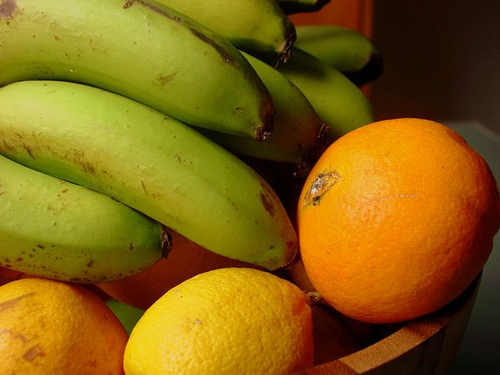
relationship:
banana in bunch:
[0, 0, 278, 143] [0, 1, 385, 284]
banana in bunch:
[0, 79, 301, 270] [0, 1, 385, 284]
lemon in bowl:
[122, 268, 314, 374] [296, 243, 493, 374]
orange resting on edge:
[298, 118, 499, 324] [399, 263, 486, 352]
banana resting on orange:
[0, 157, 171, 283] [1, 274, 130, 374]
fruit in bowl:
[0, 0, 497, 372] [296, 243, 493, 374]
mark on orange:
[0, 290, 31, 327] [1, 274, 130, 374]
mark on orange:
[26, 343, 47, 364] [1, 274, 130, 374]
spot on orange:
[311, 175, 324, 196] [298, 118, 499, 324]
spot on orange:
[311, 193, 322, 207] [298, 118, 499, 324]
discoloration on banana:
[185, 25, 236, 68] [0, 0, 278, 143]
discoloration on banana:
[257, 195, 278, 217] [0, 79, 301, 270]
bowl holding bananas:
[296, 243, 493, 374] [0, 1, 385, 284]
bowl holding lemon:
[296, 243, 493, 374] [122, 268, 314, 374]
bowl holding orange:
[296, 243, 493, 374] [298, 118, 499, 324]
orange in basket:
[298, 118, 499, 324] [296, 243, 493, 374]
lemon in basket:
[122, 268, 314, 374] [296, 243, 493, 374]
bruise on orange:
[304, 171, 343, 205] [298, 118, 499, 324]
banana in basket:
[0, 0, 278, 143] [296, 243, 493, 374]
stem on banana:
[255, 124, 276, 142] [0, 0, 278, 143]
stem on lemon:
[297, 287, 310, 301] [122, 268, 314, 374]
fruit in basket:
[0, 0, 497, 372] [296, 243, 493, 374]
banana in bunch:
[0, 157, 171, 283] [0, 1, 385, 284]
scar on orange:
[304, 171, 343, 205] [298, 118, 499, 324]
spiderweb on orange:
[304, 171, 343, 205] [298, 118, 499, 324]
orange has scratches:
[298, 118, 499, 324] [357, 189, 460, 213]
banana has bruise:
[0, 0, 278, 143] [304, 171, 343, 205]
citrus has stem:
[122, 268, 314, 374] [297, 287, 310, 301]